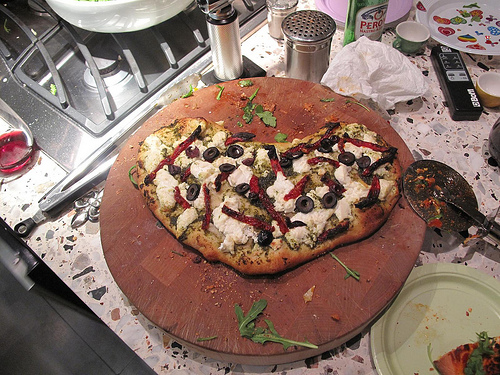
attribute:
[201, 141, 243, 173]
olives — black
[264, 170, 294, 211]
cheese — melted, white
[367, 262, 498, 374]
plate — white, light green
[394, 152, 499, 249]
cutter — dirty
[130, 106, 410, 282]
pizza — brown, cooked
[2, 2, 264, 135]
burner — silver, black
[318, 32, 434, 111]
napkin — white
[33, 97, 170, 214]
tongs — silver, black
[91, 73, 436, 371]
board — wooden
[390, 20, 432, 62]
green cup — small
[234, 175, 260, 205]
olive — black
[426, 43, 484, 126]
tv remote — black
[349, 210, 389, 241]
crust — brown